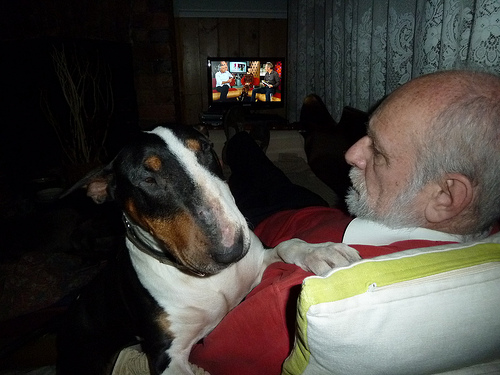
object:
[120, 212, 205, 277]
collar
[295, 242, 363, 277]
paw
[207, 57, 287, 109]
television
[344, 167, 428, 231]
beard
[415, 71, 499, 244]
hair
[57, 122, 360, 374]
dog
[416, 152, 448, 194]
ground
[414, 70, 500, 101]
bald headed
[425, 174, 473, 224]
ear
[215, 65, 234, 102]
people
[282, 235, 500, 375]
pillow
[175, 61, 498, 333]
man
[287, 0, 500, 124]
curtains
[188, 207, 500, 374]
shirt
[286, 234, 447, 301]
shoulder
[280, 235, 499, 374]
couch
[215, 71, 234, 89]
shirt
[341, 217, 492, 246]
collar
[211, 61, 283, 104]
show